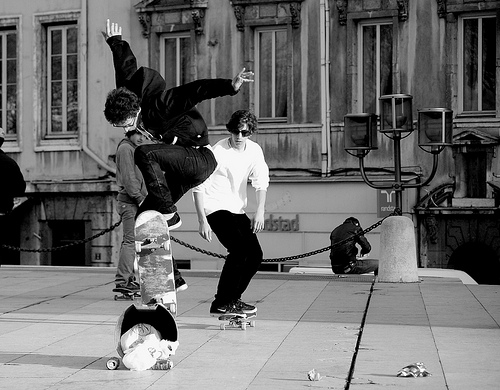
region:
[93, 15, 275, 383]
group of skate boarders skating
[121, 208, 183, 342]
skate board of one skater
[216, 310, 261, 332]
skate board of other skater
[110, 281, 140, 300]
skate board of additional skater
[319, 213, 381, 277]
person sitting on ledge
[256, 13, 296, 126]
window on nearby building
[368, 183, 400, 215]
a plaque on the building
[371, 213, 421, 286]
concrete structure on ground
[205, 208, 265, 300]
pants on skate boarder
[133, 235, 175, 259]
wheels on skate board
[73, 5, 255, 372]
teen doing a skateboard trick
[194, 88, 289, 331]
teen riding a skateboard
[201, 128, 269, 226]
teen wearing a white shirt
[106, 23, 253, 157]
teen wearing a black hoodie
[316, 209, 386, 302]
person sitting down in back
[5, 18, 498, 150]
series of windows on building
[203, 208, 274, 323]
teen wearing black pants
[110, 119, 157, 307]
teen watching others skateboard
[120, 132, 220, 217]
teen wearing black pants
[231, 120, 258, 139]
teen wearing sunglasses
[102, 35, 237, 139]
the man is wearing a black hoodie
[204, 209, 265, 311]
the boy is wearing long pants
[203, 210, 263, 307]
the pants are black in tone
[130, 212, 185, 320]
the skateboard is straight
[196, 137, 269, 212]
the young man is wearing long sleeve shirt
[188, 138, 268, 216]
the shirt is white in color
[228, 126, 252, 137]
the boy is wearing glasses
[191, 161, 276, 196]
the sleeves are rolled up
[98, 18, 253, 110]
the man has his arms spread open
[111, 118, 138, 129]
the man is wearing glasses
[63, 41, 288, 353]
three boys riding skateboards on the sidewalk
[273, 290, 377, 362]
grey stone tiles of the sidewalk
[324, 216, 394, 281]
a man sitting on a concrete wall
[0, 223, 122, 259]
black metal chain between two conrete posts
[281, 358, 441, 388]
two piece of trash on the sidewalk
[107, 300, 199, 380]
a trash can turned on it's side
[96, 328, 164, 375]
trash spilling out of the overturned trash can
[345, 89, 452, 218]
street lights on top of a concrete pillar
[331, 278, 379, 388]
a large crack between the sidewalk tiles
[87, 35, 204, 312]
a boy performing a skateboard trick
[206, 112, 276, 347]
a young man riding a skateboard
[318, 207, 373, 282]
a person sitting down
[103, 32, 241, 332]
a young man riding over a garbage can on a skateboard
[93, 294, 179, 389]
a garbage can turned over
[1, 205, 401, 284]
a long black chain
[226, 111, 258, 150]
a young man wearing sunglasses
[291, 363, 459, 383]
garbage on the ground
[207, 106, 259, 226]
a man wearing a white shirt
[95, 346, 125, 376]
a drink can on the ground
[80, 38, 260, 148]
a young man with his arms out